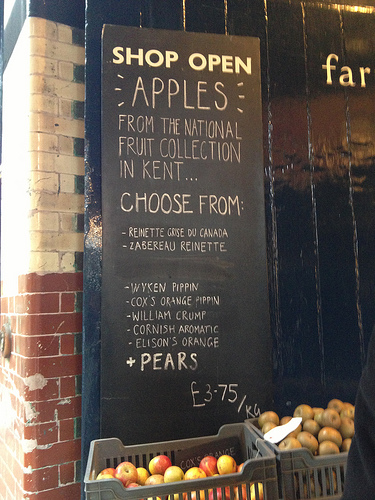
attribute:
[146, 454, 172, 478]
apple — red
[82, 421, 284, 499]
bin — gray, plastic, grey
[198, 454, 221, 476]
apple — red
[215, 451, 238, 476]
apple — yellow, green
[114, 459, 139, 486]
apple — red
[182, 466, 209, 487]
apple — yellow, green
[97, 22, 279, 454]
poster — black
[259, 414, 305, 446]
tag — white, small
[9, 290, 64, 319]
brick — red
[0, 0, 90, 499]
wall — brick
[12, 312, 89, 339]
brick — red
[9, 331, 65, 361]
brick — red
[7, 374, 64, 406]
brick — red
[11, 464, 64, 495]
brick — red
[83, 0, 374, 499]
wall — black, wooden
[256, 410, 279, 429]
apple — brown, pale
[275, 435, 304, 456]
apple — brown, pale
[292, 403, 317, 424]
apple — brown, pale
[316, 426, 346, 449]
apple — brown, pale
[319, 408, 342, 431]
apple — brown, pale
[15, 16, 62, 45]
brick — white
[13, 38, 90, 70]
brick — white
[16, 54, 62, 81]
brick — white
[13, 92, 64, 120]
brick — white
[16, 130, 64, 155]
brick — white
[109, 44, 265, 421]
writing — white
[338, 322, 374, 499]
sleeve — gray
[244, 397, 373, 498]
crate — plastic, grey, gray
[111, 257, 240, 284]
variety — erased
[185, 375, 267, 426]
price — 3.75 pounds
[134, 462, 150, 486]
apple — green, yellow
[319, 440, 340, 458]
pear — brown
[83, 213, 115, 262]
spot — white